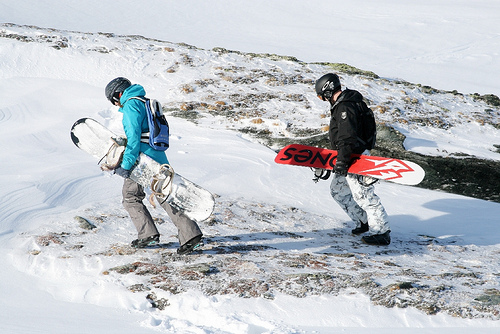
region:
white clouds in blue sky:
[447, 25, 472, 52]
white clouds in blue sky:
[390, 13, 450, 58]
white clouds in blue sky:
[328, 21, 389, 46]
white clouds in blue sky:
[451, 38, 482, 78]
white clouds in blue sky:
[253, 10, 303, 43]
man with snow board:
[90, 71, 200, 266]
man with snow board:
[277, 51, 414, 242]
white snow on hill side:
[17, 271, 74, 311]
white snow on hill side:
[16, 55, 46, 81]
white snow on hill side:
[11, 72, 59, 113]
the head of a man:
[303, 67, 353, 126]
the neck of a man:
[317, 81, 349, 116]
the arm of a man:
[321, 45, 398, 179]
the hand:
[320, 147, 368, 184]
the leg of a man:
[346, 153, 399, 246]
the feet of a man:
[334, 208, 446, 253]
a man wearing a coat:
[314, 70, 418, 170]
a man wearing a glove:
[324, 148, 364, 190]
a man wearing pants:
[313, 141, 408, 265]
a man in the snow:
[271, 24, 418, 229]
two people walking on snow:
[56, 64, 436, 297]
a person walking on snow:
[53, 68, 192, 274]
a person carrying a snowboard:
[260, 63, 457, 269]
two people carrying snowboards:
[66, 53, 439, 269]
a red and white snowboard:
[256, 129, 472, 226]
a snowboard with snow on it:
[58, 118, 279, 240]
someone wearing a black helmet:
[296, 56, 356, 113]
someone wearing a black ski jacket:
[298, 64, 401, 184]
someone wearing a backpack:
[92, 65, 204, 190]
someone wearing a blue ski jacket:
[83, 69, 215, 224]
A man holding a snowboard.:
[70, 78, 218, 251]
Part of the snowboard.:
[69, 119, 99, 151]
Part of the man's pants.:
[132, 205, 147, 230]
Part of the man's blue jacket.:
[128, 112, 135, 130]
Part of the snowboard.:
[275, 142, 312, 168]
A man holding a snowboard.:
[276, 72, 426, 246]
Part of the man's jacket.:
[342, 112, 354, 139]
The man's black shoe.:
[362, 230, 392, 245]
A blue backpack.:
[146, 99, 169, 151]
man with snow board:
[61, 79, 219, 286]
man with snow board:
[247, 63, 409, 240]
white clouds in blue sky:
[412, 19, 430, 37]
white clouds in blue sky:
[417, 42, 455, 83]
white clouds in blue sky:
[420, 12, 481, 76]